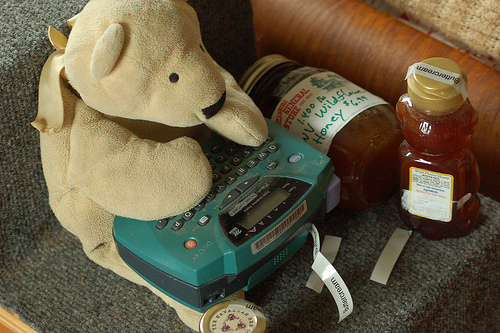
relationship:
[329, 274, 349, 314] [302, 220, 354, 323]
writing printed on sticker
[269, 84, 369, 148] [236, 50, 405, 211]
writing printed on bottle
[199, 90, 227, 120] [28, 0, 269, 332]
nose sewn onto bear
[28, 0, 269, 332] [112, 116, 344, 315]
bear holding labeler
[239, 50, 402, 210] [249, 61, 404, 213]
honey jars containing honey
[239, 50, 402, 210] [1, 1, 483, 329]
honey jars lying on top of chair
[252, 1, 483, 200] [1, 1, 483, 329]
side attached to chair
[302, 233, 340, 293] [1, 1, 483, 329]
paper lying on top of chair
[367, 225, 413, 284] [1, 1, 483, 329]
paper lying on top of chair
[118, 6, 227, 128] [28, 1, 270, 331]
face belonging to bear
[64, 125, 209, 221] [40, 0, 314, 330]
arm of teddy bear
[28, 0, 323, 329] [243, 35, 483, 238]
bear with honey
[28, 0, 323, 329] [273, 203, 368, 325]
bear printing out labels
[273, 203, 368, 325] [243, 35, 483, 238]
labels put on honey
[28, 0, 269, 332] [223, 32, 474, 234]
bear and honey jars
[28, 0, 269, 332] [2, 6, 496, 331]
bear on stairs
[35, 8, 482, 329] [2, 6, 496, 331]
collectables on stairs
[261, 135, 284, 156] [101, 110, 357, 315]
key on keyboard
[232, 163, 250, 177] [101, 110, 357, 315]
key on keyboard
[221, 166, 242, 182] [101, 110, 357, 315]
key on keyboard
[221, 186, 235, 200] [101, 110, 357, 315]
key on keyboard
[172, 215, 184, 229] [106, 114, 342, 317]
key on keyboard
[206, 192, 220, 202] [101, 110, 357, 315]
key on keyboard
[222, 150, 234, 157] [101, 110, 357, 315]
key on keyboard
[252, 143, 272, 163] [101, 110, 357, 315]
key on keyboard